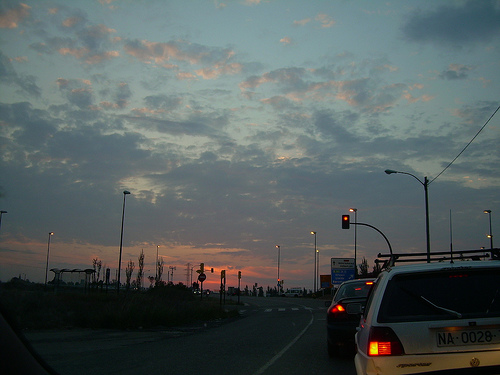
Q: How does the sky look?
A: Cloudy.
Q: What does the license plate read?
A: NA-0028.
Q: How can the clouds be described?
A: Thick.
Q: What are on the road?
A: Vehicles.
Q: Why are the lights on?
A: It's dark.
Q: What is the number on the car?
A: 0028.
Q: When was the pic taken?
A: In the evening.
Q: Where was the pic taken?
A: On the road.